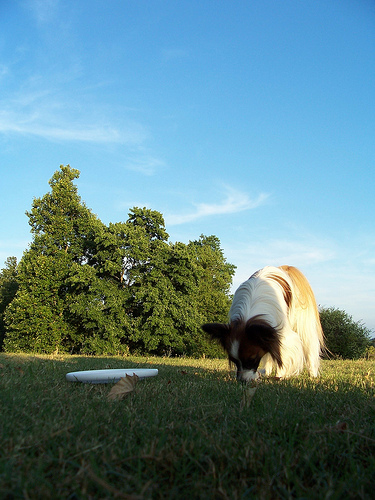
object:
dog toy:
[66, 368, 159, 384]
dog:
[200, 264, 336, 385]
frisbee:
[66, 368, 159, 383]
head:
[200, 316, 286, 386]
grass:
[0, 409, 45, 499]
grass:
[324, 404, 373, 461]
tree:
[318, 308, 372, 364]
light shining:
[283, 270, 321, 377]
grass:
[0, 354, 52, 428]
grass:
[126, 413, 173, 479]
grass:
[347, 354, 375, 389]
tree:
[0, 163, 234, 361]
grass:
[281, 391, 315, 440]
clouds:
[0, 69, 148, 146]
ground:
[0, 352, 375, 499]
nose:
[236, 373, 242, 382]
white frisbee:
[66, 368, 159, 383]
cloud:
[158, 178, 268, 228]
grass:
[172, 355, 212, 382]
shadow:
[0, 358, 374, 500]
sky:
[0, 0, 375, 335]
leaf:
[106, 372, 139, 407]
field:
[0, 353, 375, 498]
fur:
[237, 291, 273, 322]